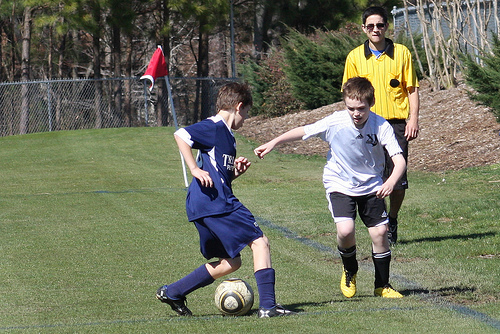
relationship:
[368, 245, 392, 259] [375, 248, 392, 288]
white stripe decorating black sock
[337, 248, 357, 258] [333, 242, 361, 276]
stripe decorating black sock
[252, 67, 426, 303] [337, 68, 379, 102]
boy with hair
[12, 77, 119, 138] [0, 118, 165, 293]
fence around field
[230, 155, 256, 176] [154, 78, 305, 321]
hand on person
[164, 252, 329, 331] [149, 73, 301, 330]
feet on person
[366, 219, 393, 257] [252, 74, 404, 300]
leg on boy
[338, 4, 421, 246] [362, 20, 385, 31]
man wearing sunglasses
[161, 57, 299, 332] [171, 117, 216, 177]
person has arm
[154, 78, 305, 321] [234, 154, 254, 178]
person has hand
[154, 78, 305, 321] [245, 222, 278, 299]
person has leg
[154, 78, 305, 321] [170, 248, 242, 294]
person has leg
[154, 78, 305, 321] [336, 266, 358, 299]
person has foot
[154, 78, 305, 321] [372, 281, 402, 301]
person has foot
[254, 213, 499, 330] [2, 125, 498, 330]
line on grass